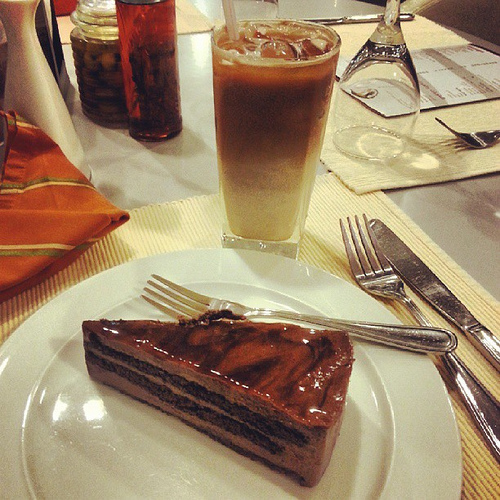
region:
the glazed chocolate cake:
[80, 313, 347, 480]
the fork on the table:
[138, 271, 457, 367]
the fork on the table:
[337, 210, 497, 447]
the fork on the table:
[432, 113, 499, 155]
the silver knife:
[365, 216, 497, 373]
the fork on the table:
[252, 304, 451, 360]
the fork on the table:
[400, 296, 499, 456]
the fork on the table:
[465, 324, 498, 366]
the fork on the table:
[350, 8, 410, 30]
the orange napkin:
[0, 109, 121, 299]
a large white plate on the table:
[1, 248, 461, 498]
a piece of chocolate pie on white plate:
[80, 318, 355, 485]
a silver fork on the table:
[140, 271, 457, 355]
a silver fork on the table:
[337, 212, 499, 462]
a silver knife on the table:
[366, 217, 498, 372]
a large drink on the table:
[210, 18, 341, 258]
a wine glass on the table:
[333, 2, 420, 169]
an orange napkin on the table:
[0, 110, 129, 303]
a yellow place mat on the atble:
[0, 172, 499, 498]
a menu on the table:
[328, 43, 499, 117]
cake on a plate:
[69, 313, 120, 413]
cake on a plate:
[129, 299, 161, 406]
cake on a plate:
[155, 288, 219, 426]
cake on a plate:
[197, 309, 264, 451]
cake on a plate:
[240, 292, 294, 450]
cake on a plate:
[277, 308, 354, 489]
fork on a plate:
[107, 255, 474, 383]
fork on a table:
[300, 212, 497, 444]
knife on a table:
[356, 205, 497, 359]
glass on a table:
[190, 23, 352, 255]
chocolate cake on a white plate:
[75, 296, 352, 486]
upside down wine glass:
[331, 0, 417, 167]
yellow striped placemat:
[139, 207, 205, 244]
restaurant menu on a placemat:
[341, 42, 498, 110]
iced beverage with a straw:
[211, 0, 339, 258]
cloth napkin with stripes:
[0, 112, 130, 282]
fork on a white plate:
[136, 272, 456, 362]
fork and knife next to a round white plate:
[338, 210, 499, 497]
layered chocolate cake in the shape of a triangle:
[78, 315, 353, 484]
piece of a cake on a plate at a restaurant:
[3, 232, 473, 497]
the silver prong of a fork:
[138, 293, 187, 323]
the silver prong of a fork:
[143, 281, 204, 314]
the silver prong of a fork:
[151, 272, 213, 307]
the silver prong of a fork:
[332, 217, 361, 276]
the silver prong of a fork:
[345, 214, 371, 275]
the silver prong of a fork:
[352, 211, 381, 273]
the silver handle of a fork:
[247, 301, 457, 358]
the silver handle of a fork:
[405, 302, 498, 451]